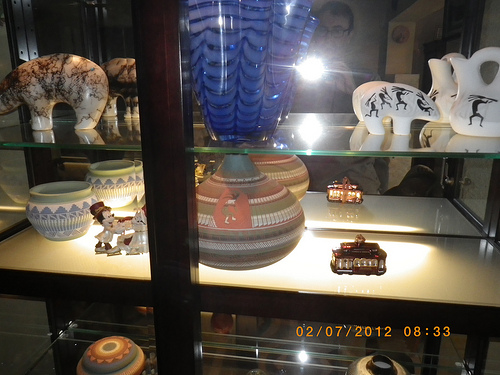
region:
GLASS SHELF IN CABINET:
[0, 96, 499, 170]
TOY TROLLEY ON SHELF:
[327, 234, 387, 275]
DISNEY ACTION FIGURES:
[78, 201, 145, 252]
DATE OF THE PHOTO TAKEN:
[287, 310, 455, 350]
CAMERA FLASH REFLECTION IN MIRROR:
[298, 48, 319, 80]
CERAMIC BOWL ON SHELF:
[185, 166, 310, 272]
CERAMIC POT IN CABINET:
[87, 333, 159, 374]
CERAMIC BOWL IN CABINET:
[14, 180, 96, 242]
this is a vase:
[27, 181, 89, 235]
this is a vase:
[89, 164, 144, 196]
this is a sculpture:
[321, 87, 448, 142]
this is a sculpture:
[449, 50, 497, 147]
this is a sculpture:
[24, 54, 109, 110]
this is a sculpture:
[103, 57, 135, 89]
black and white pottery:
[354, 31, 498, 141]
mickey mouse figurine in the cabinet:
[90, 200, 133, 260]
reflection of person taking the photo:
[293, 1, 368, 111]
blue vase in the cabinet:
[188, 6, 320, 143]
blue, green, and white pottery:
[25, 182, 97, 242]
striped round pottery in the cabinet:
[193, 159, 308, 274]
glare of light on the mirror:
[294, 52, 327, 88]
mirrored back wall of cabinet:
[39, 7, 490, 229]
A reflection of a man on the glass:
[316, 3, 382, 112]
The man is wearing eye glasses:
[315, 23, 355, 38]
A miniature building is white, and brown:
[328, 234, 387, 273]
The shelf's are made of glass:
[0, 110, 495, 370]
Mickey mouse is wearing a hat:
[85, 200, 105, 215]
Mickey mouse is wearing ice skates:
[95, 242, 120, 252]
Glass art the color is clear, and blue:
[177, 0, 318, 143]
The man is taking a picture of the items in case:
[295, 0, 376, 111]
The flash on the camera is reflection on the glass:
[295, 56, 325, 81]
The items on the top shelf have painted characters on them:
[350, 45, 499, 137]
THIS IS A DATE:
[281, 318, 388, 360]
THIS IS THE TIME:
[406, 325, 469, 340]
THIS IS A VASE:
[81, 333, 138, 367]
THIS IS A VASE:
[33, 175, 92, 237]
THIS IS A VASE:
[256, 117, 312, 198]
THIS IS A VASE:
[189, 147, 292, 269]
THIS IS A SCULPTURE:
[356, 78, 437, 120]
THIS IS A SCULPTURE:
[429, 57, 445, 102]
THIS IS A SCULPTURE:
[451, 52, 497, 130]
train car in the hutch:
[331, 236, 389, 278]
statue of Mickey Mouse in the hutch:
[86, 197, 126, 258]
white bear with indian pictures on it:
[355, 79, 437, 138]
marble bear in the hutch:
[6, 47, 110, 135]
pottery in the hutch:
[26, 176, 97, 243]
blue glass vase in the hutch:
[182, 2, 311, 150]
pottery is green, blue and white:
[23, 177, 100, 242]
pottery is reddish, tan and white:
[194, 155, 303, 270]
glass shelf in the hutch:
[195, 106, 491, 170]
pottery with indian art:
[444, 44, 498, 138]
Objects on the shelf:
[7, 0, 498, 142]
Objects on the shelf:
[16, 162, 495, 298]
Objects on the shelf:
[9, 143, 494, 307]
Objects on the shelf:
[19, 148, 497, 303]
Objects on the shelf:
[10, 143, 497, 301]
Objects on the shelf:
[18, 160, 156, 279]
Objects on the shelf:
[13, 149, 163, 279]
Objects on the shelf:
[195, 151, 412, 291]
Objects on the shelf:
[192, 153, 402, 288]